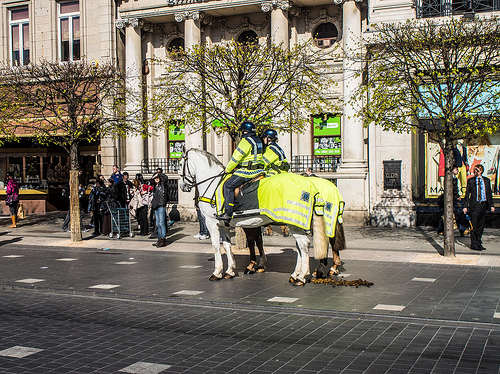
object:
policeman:
[212, 121, 266, 224]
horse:
[175, 148, 332, 287]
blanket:
[209, 172, 326, 232]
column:
[120, 18, 145, 174]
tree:
[349, 0, 500, 256]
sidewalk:
[1, 212, 500, 257]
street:
[3, 248, 499, 373]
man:
[463, 163, 494, 250]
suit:
[463, 176, 495, 250]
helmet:
[236, 120, 257, 134]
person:
[151, 172, 167, 247]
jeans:
[154, 207, 169, 239]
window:
[310, 21, 341, 50]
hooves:
[292, 274, 308, 285]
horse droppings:
[313, 274, 376, 289]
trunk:
[444, 144, 456, 259]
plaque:
[382, 160, 403, 191]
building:
[367, 0, 500, 232]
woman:
[5, 169, 21, 228]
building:
[116, 0, 367, 224]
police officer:
[258, 128, 291, 176]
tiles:
[373, 303, 408, 311]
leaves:
[379, 100, 397, 119]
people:
[86, 166, 171, 248]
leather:
[151, 172, 168, 210]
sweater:
[7, 179, 19, 205]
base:
[69, 169, 82, 242]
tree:
[1, 58, 164, 243]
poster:
[312, 116, 342, 156]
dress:
[439, 146, 447, 176]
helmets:
[262, 128, 278, 141]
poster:
[167, 119, 188, 159]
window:
[164, 36, 187, 62]